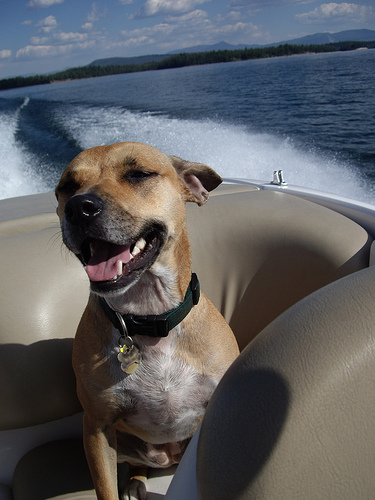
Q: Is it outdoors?
A: Yes, it is outdoors.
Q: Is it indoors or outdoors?
A: It is outdoors.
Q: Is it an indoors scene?
A: No, it is outdoors.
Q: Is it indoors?
A: No, it is outdoors.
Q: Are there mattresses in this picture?
A: No, there are no mattresses.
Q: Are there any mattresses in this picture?
A: No, there are no mattresses.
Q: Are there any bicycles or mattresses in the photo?
A: No, there are no mattresses or bicycles.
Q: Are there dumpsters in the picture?
A: No, there are no dumpsters.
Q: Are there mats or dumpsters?
A: No, there are no dumpsters or mats.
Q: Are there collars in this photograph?
A: Yes, there is a collar.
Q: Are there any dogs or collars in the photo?
A: Yes, there is a collar.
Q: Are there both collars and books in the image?
A: No, there is a collar but no books.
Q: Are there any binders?
A: No, there are no binders.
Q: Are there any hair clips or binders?
A: No, there are no binders or hair clips.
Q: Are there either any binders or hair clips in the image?
A: No, there are no binders or hair clips.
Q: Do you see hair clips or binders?
A: No, there are no binders or hair clips.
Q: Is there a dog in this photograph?
A: Yes, there is a dog.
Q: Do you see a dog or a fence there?
A: Yes, there is a dog.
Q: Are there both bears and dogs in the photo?
A: No, there is a dog but no bears.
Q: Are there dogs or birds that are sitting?
A: Yes, the dog is sitting.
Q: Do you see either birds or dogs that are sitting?
A: Yes, the dog is sitting.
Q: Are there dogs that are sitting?
A: Yes, there is a dog that is sitting.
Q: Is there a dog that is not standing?
A: Yes, there is a dog that is sitting.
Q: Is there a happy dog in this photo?
A: Yes, there is a happy dog.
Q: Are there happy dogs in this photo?
A: Yes, there is a happy dog.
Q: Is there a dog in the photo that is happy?
A: Yes, there is a dog that is happy.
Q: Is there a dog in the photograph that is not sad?
A: Yes, there is a happy dog.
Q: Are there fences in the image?
A: No, there are no fences.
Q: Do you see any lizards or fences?
A: No, there are no fences or lizards.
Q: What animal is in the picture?
A: The animal is a dog.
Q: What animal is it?
A: The animal is a dog.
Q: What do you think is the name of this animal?
A: This is a dog.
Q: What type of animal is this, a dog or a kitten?
A: This is a dog.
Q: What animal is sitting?
A: The animal is a dog.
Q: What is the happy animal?
A: The animal is a dog.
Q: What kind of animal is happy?
A: The animal is a dog.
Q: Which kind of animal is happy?
A: The animal is a dog.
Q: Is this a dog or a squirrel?
A: This is a dog.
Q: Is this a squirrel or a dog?
A: This is a dog.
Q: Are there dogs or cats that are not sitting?
A: No, there is a dog but it is sitting.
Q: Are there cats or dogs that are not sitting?
A: No, there is a dog but it is sitting.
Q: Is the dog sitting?
A: Yes, the dog is sitting.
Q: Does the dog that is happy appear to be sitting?
A: Yes, the dog is sitting.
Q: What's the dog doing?
A: The dog is sitting.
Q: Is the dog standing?
A: No, the dog is sitting.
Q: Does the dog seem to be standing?
A: No, the dog is sitting.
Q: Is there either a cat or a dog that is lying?
A: No, there is a dog but it is sitting.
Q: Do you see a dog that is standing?
A: No, there is a dog but it is sitting.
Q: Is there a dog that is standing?
A: No, there is a dog but it is sitting.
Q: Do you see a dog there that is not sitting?
A: No, there is a dog but it is sitting.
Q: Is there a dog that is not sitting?
A: No, there is a dog but it is sitting.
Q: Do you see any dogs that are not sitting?
A: No, there is a dog but it is sitting.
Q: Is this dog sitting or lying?
A: The dog is sitting.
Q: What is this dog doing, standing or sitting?
A: The dog is sitting.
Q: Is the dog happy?
A: Yes, the dog is happy.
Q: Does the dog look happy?
A: Yes, the dog is happy.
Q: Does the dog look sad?
A: No, the dog is happy.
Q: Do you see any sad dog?
A: No, there is a dog but it is happy.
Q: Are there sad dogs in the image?
A: No, there is a dog but it is happy.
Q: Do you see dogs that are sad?
A: No, there is a dog but it is happy.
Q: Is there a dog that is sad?
A: No, there is a dog but it is happy.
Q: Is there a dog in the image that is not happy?
A: No, there is a dog but it is happy.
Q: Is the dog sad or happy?
A: The dog is happy.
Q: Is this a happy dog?
A: Yes, this is a happy dog.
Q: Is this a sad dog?
A: No, this is a happy dog.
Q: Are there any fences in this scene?
A: No, there are no fences.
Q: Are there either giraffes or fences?
A: No, there are no fences or giraffes.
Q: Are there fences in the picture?
A: No, there are no fences.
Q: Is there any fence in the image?
A: No, there are no fences.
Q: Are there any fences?
A: No, there are no fences.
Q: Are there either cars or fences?
A: No, there are no fences or cars.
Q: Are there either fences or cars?
A: No, there are no fences or cars.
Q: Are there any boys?
A: No, there are no boys.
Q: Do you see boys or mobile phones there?
A: No, there are no boys or mobile phones.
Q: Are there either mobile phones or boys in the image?
A: No, there are no boys or mobile phones.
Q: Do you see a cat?
A: No, there are no cats.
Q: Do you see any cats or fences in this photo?
A: No, there are no cats or fences.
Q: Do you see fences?
A: No, there are no fences.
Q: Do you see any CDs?
A: No, there are no cds.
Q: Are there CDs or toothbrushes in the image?
A: No, there are no CDs or toothbrushes.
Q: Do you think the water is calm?
A: Yes, the water is calm.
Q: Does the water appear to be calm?
A: Yes, the water is calm.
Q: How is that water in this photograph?
A: The water is calm.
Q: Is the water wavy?
A: No, the water is calm.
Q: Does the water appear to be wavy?
A: No, the water is calm.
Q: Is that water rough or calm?
A: The water is calm.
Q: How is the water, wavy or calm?
A: The water is calm.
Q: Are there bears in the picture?
A: No, there are no bears.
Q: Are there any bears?
A: No, there are no bears.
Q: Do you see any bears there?
A: No, there are no bears.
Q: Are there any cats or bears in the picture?
A: No, there are no bears or cats.